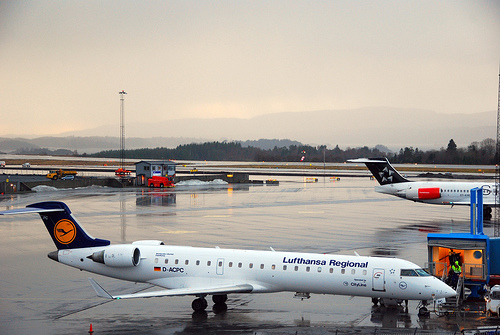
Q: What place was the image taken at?
A: It was taken at the airport.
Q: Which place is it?
A: It is an airport.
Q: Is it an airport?
A: Yes, it is an airport.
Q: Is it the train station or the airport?
A: It is the airport.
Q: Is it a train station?
A: No, it is an airport.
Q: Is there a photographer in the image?
A: No, there are no photographers.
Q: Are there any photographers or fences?
A: No, there are no photographers or fences.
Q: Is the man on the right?
A: Yes, the man is on the right of the image.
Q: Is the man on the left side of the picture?
A: No, the man is on the right of the image.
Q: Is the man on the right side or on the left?
A: The man is on the right of the image.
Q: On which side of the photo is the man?
A: The man is on the right of the image.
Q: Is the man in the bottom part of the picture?
A: Yes, the man is in the bottom of the image.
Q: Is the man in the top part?
A: No, the man is in the bottom of the image.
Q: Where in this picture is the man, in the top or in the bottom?
A: The man is in the bottom of the image.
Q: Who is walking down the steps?
A: The man is walking down the steps.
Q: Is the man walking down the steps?
A: Yes, the man is walking down the steps.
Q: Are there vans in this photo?
A: No, there are no vans.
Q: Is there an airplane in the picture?
A: Yes, there is an airplane.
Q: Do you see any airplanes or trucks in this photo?
A: Yes, there is an airplane.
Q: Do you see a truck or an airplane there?
A: Yes, there is an airplane.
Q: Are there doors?
A: Yes, there is a door.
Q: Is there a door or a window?
A: Yes, there is a door.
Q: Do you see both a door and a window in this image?
A: Yes, there are both a door and a window.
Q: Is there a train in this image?
A: No, there are no trains.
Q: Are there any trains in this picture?
A: No, there are no trains.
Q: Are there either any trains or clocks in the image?
A: No, there are no trains or clocks.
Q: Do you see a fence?
A: No, there are no fences.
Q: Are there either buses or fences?
A: No, there are no fences or buses.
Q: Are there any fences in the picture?
A: No, there are no fences.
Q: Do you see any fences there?
A: No, there are no fences.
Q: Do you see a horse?
A: No, there are no horses.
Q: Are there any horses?
A: No, there are no horses.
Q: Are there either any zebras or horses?
A: No, there are no horses or zebras.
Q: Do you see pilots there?
A: No, there are no pilots.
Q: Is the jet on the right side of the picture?
A: Yes, the jet is on the right of the image.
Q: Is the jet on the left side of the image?
A: No, the jet is on the right of the image.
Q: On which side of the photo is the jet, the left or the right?
A: The jet is on the right of the image.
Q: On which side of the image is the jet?
A: The jet is on the right of the image.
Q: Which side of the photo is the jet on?
A: The jet is on the right of the image.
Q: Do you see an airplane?
A: Yes, there is an airplane.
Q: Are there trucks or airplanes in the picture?
A: Yes, there is an airplane.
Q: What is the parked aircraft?
A: The aircraft is an airplane.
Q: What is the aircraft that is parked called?
A: The aircraft is an airplane.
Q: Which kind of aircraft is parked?
A: The aircraft is an airplane.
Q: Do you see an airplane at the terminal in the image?
A: Yes, there is an airplane at the terminal.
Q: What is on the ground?
A: The airplane is on the ground.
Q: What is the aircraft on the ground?
A: The aircraft is an airplane.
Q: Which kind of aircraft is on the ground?
A: The aircraft is an airplane.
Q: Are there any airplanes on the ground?
A: Yes, there is an airplane on the ground.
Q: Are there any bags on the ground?
A: No, there is an airplane on the ground.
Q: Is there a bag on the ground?
A: No, there is an airplane on the ground.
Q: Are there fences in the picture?
A: No, there are no fences.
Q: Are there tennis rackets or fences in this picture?
A: No, there are no fences or tennis rackets.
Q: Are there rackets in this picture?
A: No, there are no rackets.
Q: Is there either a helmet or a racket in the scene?
A: No, there are no rackets or helmets.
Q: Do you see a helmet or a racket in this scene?
A: No, there are no rackets or helmets.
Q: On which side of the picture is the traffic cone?
A: The traffic cone is on the left of the image.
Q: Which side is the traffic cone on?
A: The traffic cone is on the left of the image.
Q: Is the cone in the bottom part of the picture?
A: Yes, the cone is in the bottom of the image.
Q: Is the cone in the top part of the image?
A: No, the cone is in the bottom of the image.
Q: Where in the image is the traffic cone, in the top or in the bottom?
A: The traffic cone is in the bottom of the image.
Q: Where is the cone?
A: The cone is on the pavement.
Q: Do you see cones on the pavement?
A: Yes, there is a cone on the pavement.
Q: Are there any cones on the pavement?
A: Yes, there is a cone on the pavement.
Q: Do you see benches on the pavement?
A: No, there is a cone on the pavement.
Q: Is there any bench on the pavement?
A: No, there is a cone on the pavement.